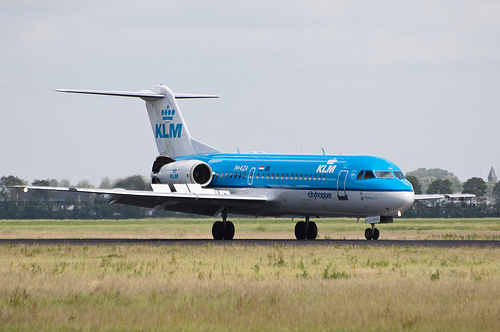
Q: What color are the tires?
A: Black.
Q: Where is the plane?
A: On the runway.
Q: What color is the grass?
A: Brown and green.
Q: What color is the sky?
A: Gray.